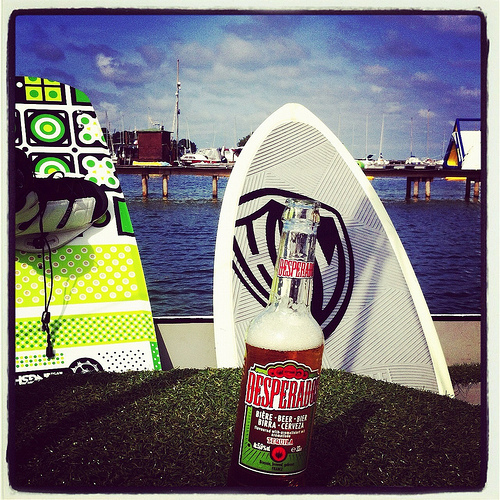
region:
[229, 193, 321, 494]
a glass bottle of tequila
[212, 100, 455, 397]
the top edge of a surfboard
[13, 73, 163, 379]
the edge of a brightly decorated board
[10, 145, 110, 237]
a black and white shoe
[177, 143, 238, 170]
a white and red boat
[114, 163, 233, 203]
a wooden pier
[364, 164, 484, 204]
a long wooden pier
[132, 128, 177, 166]
a small building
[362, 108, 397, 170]
a white boat with a mast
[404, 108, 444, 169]
two boats with masts sitting next to each other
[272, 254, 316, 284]
Desperado red and white label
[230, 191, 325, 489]
Bottle of Desperado beer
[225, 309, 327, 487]
Beer in glass bottle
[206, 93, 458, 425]
White and black surfboard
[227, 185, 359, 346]
Logo on white and black surfboard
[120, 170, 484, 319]
Blue body of water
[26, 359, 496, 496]
Hill of grass under bottle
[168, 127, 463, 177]
Boats in the distance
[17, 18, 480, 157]
Blue and white cloudy sky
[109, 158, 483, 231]
Wooden brown pier in water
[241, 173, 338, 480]
the bottle says Desperado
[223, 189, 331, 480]
this appears to be some type of beer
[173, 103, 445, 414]
a surfboard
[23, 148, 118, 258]
a foot shod in a sneaker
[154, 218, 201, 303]
the water is a magnificent blue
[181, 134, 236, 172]
a boat is in the background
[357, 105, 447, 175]
a few sail boats are moored in the background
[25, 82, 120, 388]
this board is very bright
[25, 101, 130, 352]
the board is colorful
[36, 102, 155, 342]
it is green, yellow, white, & black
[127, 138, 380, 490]
a bottled drink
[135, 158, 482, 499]
a bottle drink on the table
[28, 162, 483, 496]
a bottled drink on the table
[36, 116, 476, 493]
a table with a bottled drink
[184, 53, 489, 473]
a surfborad leaning against wall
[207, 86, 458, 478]
a white and black surfboard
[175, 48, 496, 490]
white and black surfboard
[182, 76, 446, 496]
surfboard that is white and black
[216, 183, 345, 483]
bottle of beer on turf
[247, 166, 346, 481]
bottle of beer on fake grass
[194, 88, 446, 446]
bottle of bear and surf board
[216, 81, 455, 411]
black and white surf board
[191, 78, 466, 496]
black, gray, and white surf board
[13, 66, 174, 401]
green and white surf board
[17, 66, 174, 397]
neon green surf board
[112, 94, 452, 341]
view of water and pier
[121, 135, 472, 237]
long pier in water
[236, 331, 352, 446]
clear desperado label on beer bottle